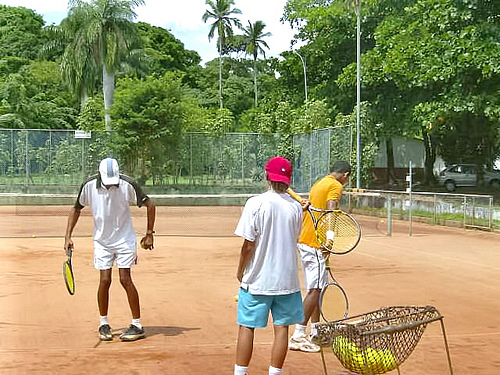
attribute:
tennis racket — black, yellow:
[57, 239, 84, 299]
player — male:
[57, 150, 160, 344]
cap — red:
[261, 150, 295, 193]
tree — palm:
[52, 4, 144, 125]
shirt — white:
[230, 188, 311, 304]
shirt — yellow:
[301, 175, 348, 247]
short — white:
[299, 246, 335, 291]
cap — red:
[243, 197, 313, 289]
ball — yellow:
[307, 306, 406, 375]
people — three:
[94, 141, 353, 375]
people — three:
[74, 214, 338, 375]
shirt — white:
[248, 215, 326, 319]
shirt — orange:
[326, 178, 341, 258]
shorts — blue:
[242, 295, 302, 375]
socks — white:
[226, 341, 270, 375]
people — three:
[49, 145, 350, 375]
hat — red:
[262, 148, 295, 268]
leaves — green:
[9, 54, 415, 194]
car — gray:
[432, 135, 476, 223]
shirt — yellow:
[320, 165, 329, 234]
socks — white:
[89, 285, 150, 355]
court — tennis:
[0, 191, 498, 373]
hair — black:
[330, 155, 356, 174]